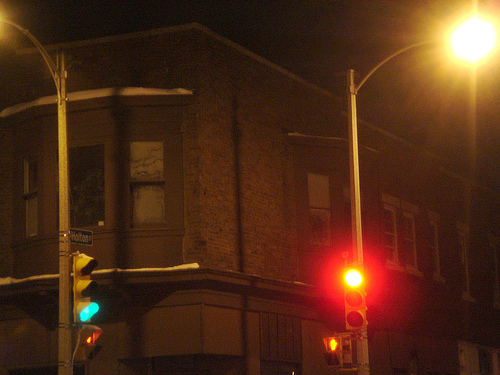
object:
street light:
[431, 5, 499, 76]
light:
[337, 265, 375, 290]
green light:
[76, 302, 100, 322]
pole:
[55, 106, 71, 374]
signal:
[342, 251, 370, 332]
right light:
[343, 268, 364, 287]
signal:
[71, 250, 101, 326]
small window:
[257, 312, 304, 374]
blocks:
[259, 313, 302, 363]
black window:
[70, 145, 105, 226]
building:
[1, 23, 500, 375]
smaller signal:
[323, 334, 343, 354]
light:
[323, 337, 340, 354]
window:
[21, 155, 43, 239]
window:
[305, 169, 333, 245]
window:
[381, 205, 399, 268]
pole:
[344, 68, 372, 374]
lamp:
[1, 11, 21, 40]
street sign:
[69, 229, 94, 246]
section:
[25, 197, 43, 236]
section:
[22, 160, 40, 193]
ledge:
[130, 222, 166, 232]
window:
[128, 137, 169, 226]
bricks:
[195, 111, 215, 119]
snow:
[1, 85, 194, 117]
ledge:
[1, 95, 191, 121]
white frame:
[383, 206, 397, 268]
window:
[401, 212, 419, 274]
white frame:
[402, 211, 417, 271]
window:
[428, 220, 442, 284]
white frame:
[426, 218, 439, 276]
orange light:
[328, 338, 339, 353]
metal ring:
[57, 229, 70, 245]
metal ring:
[56, 248, 72, 257]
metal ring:
[55, 320, 71, 329]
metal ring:
[56, 356, 72, 368]